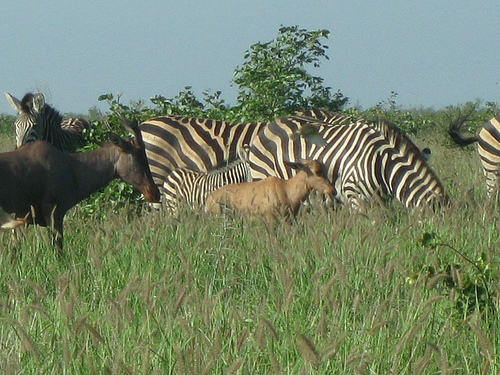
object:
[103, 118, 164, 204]
head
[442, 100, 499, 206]
animal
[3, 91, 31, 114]
ear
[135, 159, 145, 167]
eye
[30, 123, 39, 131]
eye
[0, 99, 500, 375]
grass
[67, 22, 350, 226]
bush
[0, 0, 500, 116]
sky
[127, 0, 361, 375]
middle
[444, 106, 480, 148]
tail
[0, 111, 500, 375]
field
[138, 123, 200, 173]
stripe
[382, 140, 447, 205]
neck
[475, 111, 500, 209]
back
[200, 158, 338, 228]
ram